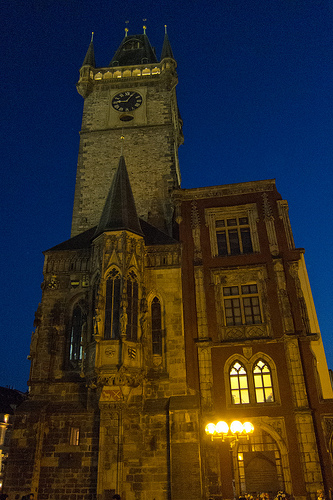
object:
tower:
[72, 16, 183, 235]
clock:
[113, 89, 146, 111]